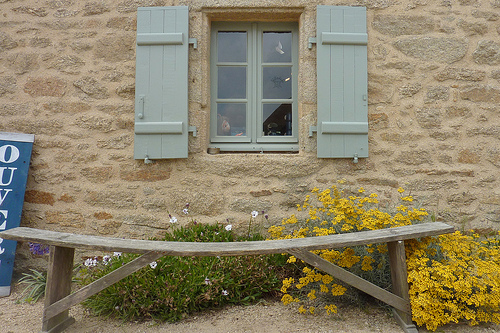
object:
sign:
[0, 134, 36, 299]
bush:
[72, 223, 297, 325]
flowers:
[461, 260, 471, 268]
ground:
[0, 282, 500, 333]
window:
[255, 98, 298, 142]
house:
[0, 0, 500, 282]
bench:
[0, 221, 456, 333]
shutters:
[314, 5, 371, 158]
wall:
[0, 0, 500, 281]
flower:
[148, 261, 156, 270]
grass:
[16, 264, 82, 305]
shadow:
[261, 103, 292, 138]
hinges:
[188, 126, 198, 139]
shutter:
[133, 6, 191, 160]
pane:
[218, 30, 245, 61]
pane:
[263, 32, 292, 64]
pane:
[217, 65, 244, 100]